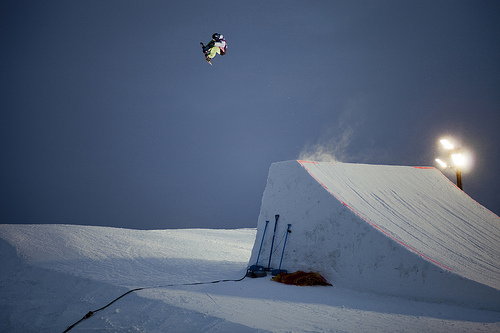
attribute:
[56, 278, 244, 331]
wire — electric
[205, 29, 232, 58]
snowboarder — high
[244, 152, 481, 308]
ramp — huge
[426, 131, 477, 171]
lights — bright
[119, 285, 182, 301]
cord — black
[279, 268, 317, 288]
fabric — orange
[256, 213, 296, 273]
poles — three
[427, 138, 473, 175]
lights — bright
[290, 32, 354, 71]
sky — clear, blue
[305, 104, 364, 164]
dust — snow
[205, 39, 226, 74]
skies — night, large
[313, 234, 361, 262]
ramp — snow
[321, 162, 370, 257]
ramp — snow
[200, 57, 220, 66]
leg — pant, green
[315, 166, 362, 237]
ramp — snow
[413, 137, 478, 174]
lights — three